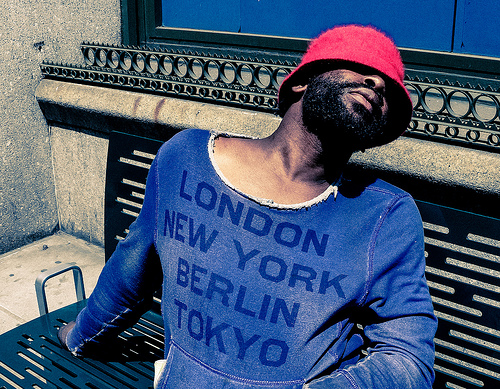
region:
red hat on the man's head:
[270, 25, 416, 153]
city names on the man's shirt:
[158, 157, 354, 379]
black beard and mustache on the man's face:
[300, 72, 389, 157]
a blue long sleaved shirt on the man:
[60, 124, 435, 385]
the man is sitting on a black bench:
[0, 139, 497, 384]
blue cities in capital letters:
[160, 164, 360, 379]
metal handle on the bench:
[32, 259, 82, 320]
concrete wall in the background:
[1, 1, 126, 258]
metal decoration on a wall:
[28, 36, 496, 151]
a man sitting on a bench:
[50, 24, 435, 378]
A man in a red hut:
[142, 34, 461, 358]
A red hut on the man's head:
[295, 23, 425, 125]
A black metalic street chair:
[10, 332, 101, 387]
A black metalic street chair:
[443, 216, 489, 377]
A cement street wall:
[32, 116, 79, 213]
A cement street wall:
[35, 6, 112, 63]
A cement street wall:
[0, 131, 50, 245]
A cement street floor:
[4, 236, 83, 307]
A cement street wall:
[51, 79, 164, 116]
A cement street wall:
[154, 99, 222, 141]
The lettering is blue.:
[171, 164, 194, 205]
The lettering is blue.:
[192, 175, 221, 214]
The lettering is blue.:
[215, 188, 245, 232]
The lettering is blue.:
[240, 199, 275, 239]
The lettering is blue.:
[268, 216, 305, 248]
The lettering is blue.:
[301, 220, 335, 257]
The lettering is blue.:
[317, 258, 358, 300]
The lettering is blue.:
[285, 256, 319, 298]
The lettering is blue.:
[256, 252, 288, 285]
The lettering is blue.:
[229, 231, 262, 276]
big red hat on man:
[275, 6, 426, 151]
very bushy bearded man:
[292, 78, 381, 155]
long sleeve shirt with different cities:
[43, 144, 450, 386]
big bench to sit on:
[5, 298, 144, 386]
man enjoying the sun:
[197, 15, 432, 245]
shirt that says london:
[172, 158, 334, 261]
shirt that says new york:
[154, 204, 344, 295]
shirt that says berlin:
[173, 251, 303, 327]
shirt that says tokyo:
[166, 297, 284, 367]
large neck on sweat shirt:
[197, 127, 355, 219]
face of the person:
[280, 25, 481, 166]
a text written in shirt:
[169, 173, 351, 375]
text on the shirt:
[165, 183, 310, 370]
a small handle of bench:
[23, 253, 105, 330]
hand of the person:
[370, 226, 448, 368]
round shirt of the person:
[182, 110, 406, 242]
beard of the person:
[318, 87, 381, 139]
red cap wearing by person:
[274, 28, 427, 88]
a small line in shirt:
[368, 195, 393, 299]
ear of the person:
[289, 79, 311, 104]